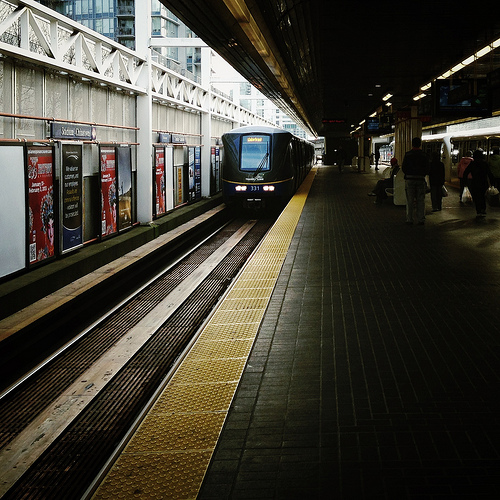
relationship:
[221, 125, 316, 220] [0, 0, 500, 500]
train at train station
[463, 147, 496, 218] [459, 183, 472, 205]
person carrying bag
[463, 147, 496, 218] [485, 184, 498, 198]
person carrying bag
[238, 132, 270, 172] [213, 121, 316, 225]
window on front of train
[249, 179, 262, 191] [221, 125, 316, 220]
number on front of train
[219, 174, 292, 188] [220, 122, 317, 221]
stripe on train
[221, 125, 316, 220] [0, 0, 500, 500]
train pulling into train station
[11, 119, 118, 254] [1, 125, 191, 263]
advertising on panels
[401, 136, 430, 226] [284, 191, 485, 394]
person on platform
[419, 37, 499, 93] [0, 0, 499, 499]
overhead light in train station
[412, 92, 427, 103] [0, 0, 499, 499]
lights in train station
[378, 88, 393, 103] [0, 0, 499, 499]
overhead light in train station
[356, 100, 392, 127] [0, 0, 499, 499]
overhead light in train station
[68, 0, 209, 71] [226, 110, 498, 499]
building outside train station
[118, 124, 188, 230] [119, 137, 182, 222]
advertisement on banner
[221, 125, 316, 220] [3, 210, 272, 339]
train on tracks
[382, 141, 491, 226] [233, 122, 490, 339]
people on side walk.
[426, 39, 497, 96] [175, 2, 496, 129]
lights on ceiling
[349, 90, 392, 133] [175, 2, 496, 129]
lights on ceiling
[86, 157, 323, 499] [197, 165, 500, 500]
part on side walk.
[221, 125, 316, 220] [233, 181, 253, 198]
train has headlight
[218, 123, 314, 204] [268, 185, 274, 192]
train has headlight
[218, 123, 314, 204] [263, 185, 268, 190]
train has headlight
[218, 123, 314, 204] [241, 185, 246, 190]
train has headlight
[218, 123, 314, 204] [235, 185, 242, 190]
train has headlight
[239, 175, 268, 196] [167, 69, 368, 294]
numbers on train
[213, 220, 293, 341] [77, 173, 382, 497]
yellow area on platform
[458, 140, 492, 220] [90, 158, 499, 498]
person on platform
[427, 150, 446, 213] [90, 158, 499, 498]
people on platform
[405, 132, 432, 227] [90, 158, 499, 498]
person on platform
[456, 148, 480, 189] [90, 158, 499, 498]
person on platform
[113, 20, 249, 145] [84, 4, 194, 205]
buildings on left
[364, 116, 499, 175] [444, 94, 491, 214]
train on right